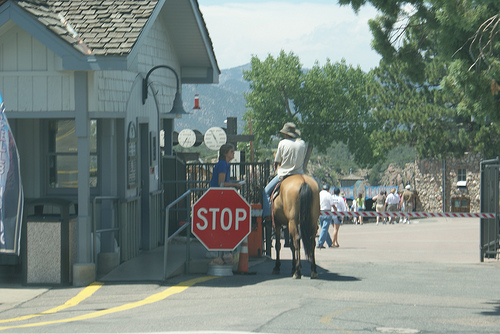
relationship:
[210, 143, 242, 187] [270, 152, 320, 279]
woman riding horse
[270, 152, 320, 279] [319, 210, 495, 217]
horse next to barrier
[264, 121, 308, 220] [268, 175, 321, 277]
woman riding horse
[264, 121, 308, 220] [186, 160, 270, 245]
woman next to fence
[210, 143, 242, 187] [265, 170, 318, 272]
woman riding horse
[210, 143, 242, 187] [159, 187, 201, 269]
woman next to fence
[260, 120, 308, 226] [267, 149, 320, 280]
man riding horse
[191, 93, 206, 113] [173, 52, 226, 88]
feeder hanging from roof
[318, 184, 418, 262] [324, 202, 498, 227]
people walking behind gate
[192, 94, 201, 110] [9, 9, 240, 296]
feeder hanging from building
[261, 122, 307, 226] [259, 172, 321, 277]
man on horse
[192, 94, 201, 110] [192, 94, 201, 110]
feeder with feeder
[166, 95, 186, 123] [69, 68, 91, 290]
light on pole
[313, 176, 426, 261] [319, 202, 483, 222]
peole walking beyond barrier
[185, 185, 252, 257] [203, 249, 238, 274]
sign on pole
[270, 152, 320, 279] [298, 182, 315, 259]
horse with black tail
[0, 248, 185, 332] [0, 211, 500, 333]
lines on road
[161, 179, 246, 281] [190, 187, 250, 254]
fence by sign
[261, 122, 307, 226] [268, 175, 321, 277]
man riding on horse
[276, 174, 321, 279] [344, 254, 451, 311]
horse on street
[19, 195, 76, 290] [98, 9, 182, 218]
trash can beside building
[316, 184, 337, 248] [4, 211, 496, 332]
peole walking on road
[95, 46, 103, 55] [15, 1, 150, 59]
shingle on roof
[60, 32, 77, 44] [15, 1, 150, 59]
shingle on roof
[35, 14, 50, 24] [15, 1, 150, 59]
shingle on roof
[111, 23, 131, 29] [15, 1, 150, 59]
shingle on roof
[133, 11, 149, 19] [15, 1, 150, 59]
shingle on roof